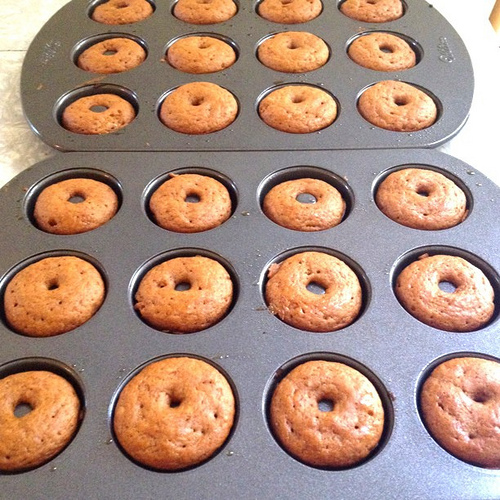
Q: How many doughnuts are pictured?
A: 24.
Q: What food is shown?
A: Doughnut.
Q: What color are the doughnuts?
A: Tan.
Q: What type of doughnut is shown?
A: Plain.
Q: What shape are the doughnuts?
A: Circular.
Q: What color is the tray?
A: Gray.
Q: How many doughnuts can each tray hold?
A: 12.